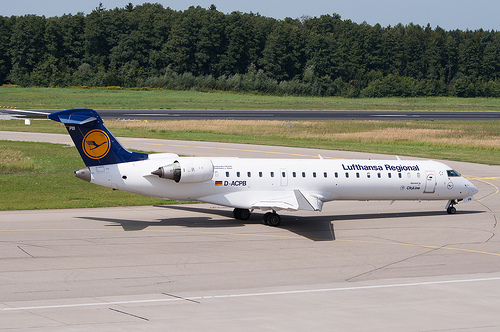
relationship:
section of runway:
[117, 208, 181, 292] [2, 210, 495, 291]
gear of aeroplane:
[258, 211, 284, 227] [46, 103, 483, 224]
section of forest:
[117, 208, 181, 292] [121, 6, 212, 85]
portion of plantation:
[8, 15, 56, 88] [3, 14, 499, 103]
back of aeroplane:
[46, 102, 282, 229] [46, 103, 483, 224]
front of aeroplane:
[335, 150, 479, 221] [46, 103, 483, 224]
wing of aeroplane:
[198, 182, 329, 219] [46, 103, 483, 224]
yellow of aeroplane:
[93, 133, 104, 147] [46, 103, 483, 224]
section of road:
[117, 208, 181, 292] [173, 137, 231, 158]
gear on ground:
[258, 211, 284, 227] [208, 222, 311, 328]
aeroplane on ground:
[46, 103, 483, 224] [208, 222, 311, 328]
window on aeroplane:
[235, 170, 242, 179] [46, 103, 483, 224]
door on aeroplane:
[423, 166, 439, 199] [47, 106, 478, 223]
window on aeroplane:
[235, 170, 242, 179] [47, 106, 478, 223]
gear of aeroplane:
[258, 211, 284, 227] [47, 106, 478, 223]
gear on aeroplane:
[228, 207, 286, 230] [47, 106, 478, 223]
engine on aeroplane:
[148, 151, 220, 185] [47, 106, 478, 223]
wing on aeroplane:
[198, 182, 329, 219] [47, 106, 478, 223]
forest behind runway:
[189, 6, 223, 85] [2, 210, 495, 291]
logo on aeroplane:
[80, 127, 111, 161] [47, 106, 478, 223]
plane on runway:
[44, 102, 484, 241] [2, 210, 495, 291]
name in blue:
[340, 160, 420, 176] [115, 153, 124, 164]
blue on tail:
[115, 153, 124, 164] [43, 107, 149, 168]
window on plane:
[235, 170, 242, 179] [44, 102, 484, 241]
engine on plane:
[148, 151, 220, 185] [44, 102, 484, 241]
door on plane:
[423, 166, 439, 199] [44, 102, 484, 241]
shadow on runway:
[68, 210, 220, 236] [2, 210, 495, 291]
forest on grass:
[189, 6, 223, 85] [120, 87, 168, 113]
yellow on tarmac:
[93, 133, 104, 147] [10, 214, 274, 312]